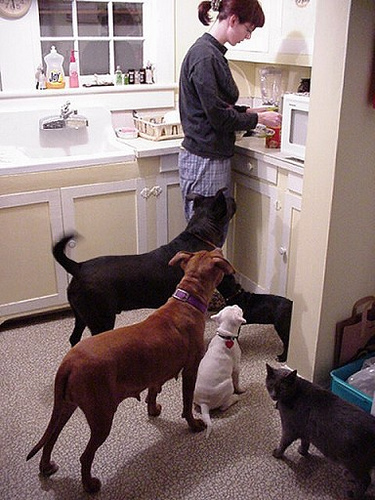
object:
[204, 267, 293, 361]
dogs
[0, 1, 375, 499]
kitchen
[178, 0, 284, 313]
woman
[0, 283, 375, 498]
floor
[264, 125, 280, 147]
can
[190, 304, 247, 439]
pet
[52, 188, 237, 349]
pet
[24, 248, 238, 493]
pet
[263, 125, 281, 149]
food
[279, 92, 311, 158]
moicrowave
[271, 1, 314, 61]
cupboard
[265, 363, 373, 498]
cat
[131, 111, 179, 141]
dish drainer